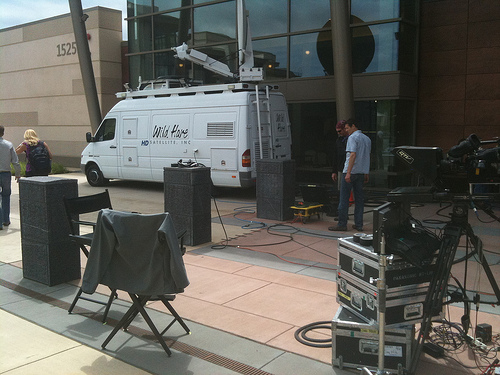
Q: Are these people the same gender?
A: No, they are both male and female.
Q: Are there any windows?
A: Yes, there are windows.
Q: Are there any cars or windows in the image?
A: Yes, there are windows.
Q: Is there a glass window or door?
A: Yes, there are glass windows.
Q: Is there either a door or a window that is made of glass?
A: Yes, the windows are made of glass.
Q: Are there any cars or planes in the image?
A: No, there are no cars or planes.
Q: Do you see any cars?
A: No, there are no cars.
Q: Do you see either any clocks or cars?
A: No, there are no cars or clocks.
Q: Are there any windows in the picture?
A: Yes, there is a window.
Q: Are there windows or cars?
A: Yes, there is a window.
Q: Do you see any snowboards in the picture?
A: No, there are no snowboards.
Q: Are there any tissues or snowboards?
A: No, there are no snowboards or tissues.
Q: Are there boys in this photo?
A: No, there are no boys.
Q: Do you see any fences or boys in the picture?
A: No, there are no boys or fences.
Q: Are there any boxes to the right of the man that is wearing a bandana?
A: No, the box is to the left of the man.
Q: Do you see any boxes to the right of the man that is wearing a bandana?
A: No, the box is to the left of the man.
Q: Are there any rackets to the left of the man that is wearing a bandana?
A: No, there is a box to the left of the man.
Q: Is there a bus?
A: No, there are no buses.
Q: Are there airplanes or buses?
A: No, there are no buses or airplanes.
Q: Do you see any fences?
A: No, there are no fences.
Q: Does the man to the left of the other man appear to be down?
A: Yes, the man is down.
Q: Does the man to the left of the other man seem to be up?
A: No, the man is down.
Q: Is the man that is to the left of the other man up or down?
A: The man is down.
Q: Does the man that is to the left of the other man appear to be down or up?
A: The man is down.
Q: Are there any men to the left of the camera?
A: Yes, there is a man to the left of the camera.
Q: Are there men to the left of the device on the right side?
A: Yes, there is a man to the left of the camera.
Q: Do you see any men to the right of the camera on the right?
A: No, the man is to the left of the camera.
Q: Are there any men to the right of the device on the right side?
A: No, the man is to the left of the camera.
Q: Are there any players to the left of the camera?
A: No, there is a man to the left of the camera.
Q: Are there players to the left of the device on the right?
A: No, there is a man to the left of the camera.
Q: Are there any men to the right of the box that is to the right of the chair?
A: Yes, there is a man to the right of the box.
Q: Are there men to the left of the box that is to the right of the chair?
A: No, the man is to the right of the box.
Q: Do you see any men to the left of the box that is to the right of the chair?
A: No, the man is to the right of the box.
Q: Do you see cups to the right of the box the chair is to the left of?
A: No, there is a man to the right of the box.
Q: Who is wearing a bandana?
A: The man is wearing a bandana.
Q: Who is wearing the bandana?
A: The man is wearing a bandana.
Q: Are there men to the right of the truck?
A: Yes, there is a man to the right of the truck.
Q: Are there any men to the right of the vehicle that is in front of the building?
A: Yes, there is a man to the right of the truck.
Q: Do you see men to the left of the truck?
A: No, the man is to the right of the truck.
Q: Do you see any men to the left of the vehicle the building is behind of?
A: No, the man is to the right of the truck.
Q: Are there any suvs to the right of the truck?
A: No, there is a man to the right of the truck.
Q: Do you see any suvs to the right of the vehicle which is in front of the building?
A: No, there is a man to the right of the truck.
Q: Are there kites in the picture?
A: No, there are no kites.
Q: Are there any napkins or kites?
A: No, there are no kites or napkins.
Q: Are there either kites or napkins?
A: No, there are no kites or napkins.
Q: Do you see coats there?
A: Yes, there is a coat.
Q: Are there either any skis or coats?
A: Yes, there is a coat.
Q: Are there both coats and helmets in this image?
A: No, there is a coat but no helmets.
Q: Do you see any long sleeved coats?
A: Yes, there is a long sleeved coat.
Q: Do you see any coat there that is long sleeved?
A: Yes, there is a coat that is long sleeved.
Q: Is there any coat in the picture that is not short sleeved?
A: Yes, there is a long sleeved coat.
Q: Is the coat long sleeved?
A: Yes, the coat is long sleeved.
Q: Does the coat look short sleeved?
A: No, the coat is long sleeved.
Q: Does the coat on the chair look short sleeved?
A: No, the coat is long sleeved.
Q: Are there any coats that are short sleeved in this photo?
A: No, there is a coat but it is long sleeved.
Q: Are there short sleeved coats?
A: No, there is a coat but it is long sleeved.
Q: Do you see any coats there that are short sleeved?
A: No, there is a coat but it is long sleeved.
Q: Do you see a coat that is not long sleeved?
A: No, there is a coat but it is long sleeved.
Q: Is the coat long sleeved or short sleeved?
A: The coat is long sleeved.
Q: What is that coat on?
A: The coat is on the chair.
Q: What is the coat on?
A: The coat is on the chair.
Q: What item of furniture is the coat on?
A: The coat is on the chair.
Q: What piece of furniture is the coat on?
A: The coat is on the chair.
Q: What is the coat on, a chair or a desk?
A: The coat is on a chair.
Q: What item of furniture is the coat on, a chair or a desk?
A: The coat is on a chair.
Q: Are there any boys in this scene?
A: No, there are no boys.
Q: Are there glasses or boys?
A: No, there are no boys or glasses.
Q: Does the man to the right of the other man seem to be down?
A: Yes, the man is down.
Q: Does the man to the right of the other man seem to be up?
A: No, the man is down.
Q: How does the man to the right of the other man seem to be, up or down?
A: The man is down.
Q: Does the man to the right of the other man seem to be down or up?
A: The man is down.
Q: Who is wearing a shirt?
A: The man is wearing a shirt.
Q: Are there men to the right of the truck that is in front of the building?
A: Yes, there is a man to the right of the truck.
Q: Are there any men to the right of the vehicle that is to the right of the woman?
A: Yes, there is a man to the right of the truck.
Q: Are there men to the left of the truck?
A: No, the man is to the right of the truck.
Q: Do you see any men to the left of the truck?
A: No, the man is to the right of the truck.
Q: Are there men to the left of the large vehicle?
A: No, the man is to the right of the truck.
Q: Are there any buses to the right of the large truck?
A: No, there is a man to the right of the truck.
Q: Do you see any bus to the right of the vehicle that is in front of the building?
A: No, there is a man to the right of the truck.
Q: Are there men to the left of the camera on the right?
A: Yes, there is a man to the left of the camera.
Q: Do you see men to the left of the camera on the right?
A: Yes, there is a man to the left of the camera.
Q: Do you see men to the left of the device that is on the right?
A: Yes, there is a man to the left of the camera.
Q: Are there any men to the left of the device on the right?
A: Yes, there is a man to the left of the camera.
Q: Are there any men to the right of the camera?
A: No, the man is to the left of the camera.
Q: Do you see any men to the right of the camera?
A: No, the man is to the left of the camera.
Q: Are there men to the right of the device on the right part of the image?
A: No, the man is to the left of the camera.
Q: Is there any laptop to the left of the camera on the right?
A: No, there is a man to the left of the camera.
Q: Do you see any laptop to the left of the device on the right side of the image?
A: No, there is a man to the left of the camera.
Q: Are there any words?
A: Yes, there are words.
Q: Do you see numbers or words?
A: Yes, there are words.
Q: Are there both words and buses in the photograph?
A: No, there are words but no buses.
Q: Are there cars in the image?
A: No, there are no cars.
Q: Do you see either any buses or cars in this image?
A: No, there are no cars or buses.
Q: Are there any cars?
A: No, there are no cars.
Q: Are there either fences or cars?
A: No, there are no cars or fences.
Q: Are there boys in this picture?
A: No, there are no boys.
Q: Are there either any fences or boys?
A: No, there are no boys or fences.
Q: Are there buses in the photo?
A: No, there are no buses.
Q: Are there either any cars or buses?
A: No, there are no buses or cars.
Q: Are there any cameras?
A: Yes, there is a camera.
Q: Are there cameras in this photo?
A: Yes, there is a camera.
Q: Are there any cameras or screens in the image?
A: Yes, there is a camera.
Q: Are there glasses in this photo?
A: No, there are no glasses.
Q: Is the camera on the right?
A: Yes, the camera is on the right of the image.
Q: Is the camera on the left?
A: No, the camera is on the right of the image.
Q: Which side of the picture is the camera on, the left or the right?
A: The camera is on the right of the image.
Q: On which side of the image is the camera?
A: The camera is on the right of the image.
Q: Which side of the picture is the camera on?
A: The camera is on the right of the image.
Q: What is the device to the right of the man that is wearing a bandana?
A: The device is a camera.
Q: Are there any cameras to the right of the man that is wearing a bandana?
A: Yes, there is a camera to the right of the man.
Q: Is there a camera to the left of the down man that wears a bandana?
A: No, the camera is to the right of the man.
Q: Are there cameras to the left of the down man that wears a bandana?
A: No, the camera is to the right of the man.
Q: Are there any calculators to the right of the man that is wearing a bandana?
A: No, there is a camera to the right of the man.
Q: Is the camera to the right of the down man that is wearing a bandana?
A: Yes, the camera is to the right of the man.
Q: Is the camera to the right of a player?
A: No, the camera is to the right of the man.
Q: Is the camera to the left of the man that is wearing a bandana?
A: No, the camera is to the right of the man.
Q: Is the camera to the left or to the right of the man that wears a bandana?
A: The camera is to the right of the man.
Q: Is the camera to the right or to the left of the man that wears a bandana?
A: The camera is to the right of the man.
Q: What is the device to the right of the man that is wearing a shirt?
A: The device is a camera.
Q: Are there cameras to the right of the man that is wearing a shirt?
A: Yes, there is a camera to the right of the man.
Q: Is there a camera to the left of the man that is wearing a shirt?
A: No, the camera is to the right of the man.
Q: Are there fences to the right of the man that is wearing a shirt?
A: No, there is a camera to the right of the man.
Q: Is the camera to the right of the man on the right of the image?
A: Yes, the camera is to the right of the man.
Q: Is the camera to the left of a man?
A: No, the camera is to the right of a man.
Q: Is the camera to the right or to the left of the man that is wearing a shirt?
A: The camera is to the right of the man.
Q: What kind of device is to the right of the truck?
A: The device is a camera.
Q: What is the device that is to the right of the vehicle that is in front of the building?
A: The device is a camera.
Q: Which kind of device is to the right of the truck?
A: The device is a camera.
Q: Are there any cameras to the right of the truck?
A: Yes, there is a camera to the right of the truck.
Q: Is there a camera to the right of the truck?
A: Yes, there is a camera to the right of the truck.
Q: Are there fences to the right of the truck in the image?
A: No, there is a camera to the right of the truck.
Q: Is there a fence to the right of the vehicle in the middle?
A: No, there is a camera to the right of the truck.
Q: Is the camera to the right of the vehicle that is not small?
A: Yes, the camera is to the right of the truck.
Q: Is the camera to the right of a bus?
A: No, the camera is to the right of the truck.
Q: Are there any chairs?
A: Yes, there is a chair.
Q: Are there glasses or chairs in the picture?
A: Yes, there is a chair.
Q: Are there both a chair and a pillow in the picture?
A: No, there is a chair but no pillows.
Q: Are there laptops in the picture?
A: No, there are no laptops.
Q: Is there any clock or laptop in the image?
A: No, there are no laptops or clocks.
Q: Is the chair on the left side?
A: Yes, the chair is on the left of the image.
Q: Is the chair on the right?
A: No, the chair is on the left of the image.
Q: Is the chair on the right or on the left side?
A: The chair is on the left of the image.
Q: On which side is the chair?
A: The chair is on the left of the image.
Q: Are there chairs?
A: Yes, there is a chair.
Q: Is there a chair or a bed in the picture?
A: Yes, there is a chair.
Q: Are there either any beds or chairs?
A: Yes, there is a chair.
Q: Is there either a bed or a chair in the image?
A: Yes, there is a chair.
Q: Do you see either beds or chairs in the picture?
A: Yes, there is a chair.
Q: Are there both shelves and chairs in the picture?
A: No, there is a chair but no shelves.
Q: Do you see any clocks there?
A: No, there are no clocks.